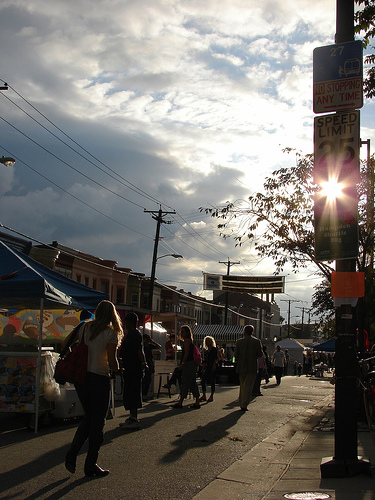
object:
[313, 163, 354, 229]
sun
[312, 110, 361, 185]
sign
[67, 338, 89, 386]
bag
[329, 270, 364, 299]
sign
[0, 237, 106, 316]
tent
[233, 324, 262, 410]
man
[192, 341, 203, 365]
backpack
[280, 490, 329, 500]
manhole cover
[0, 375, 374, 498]
sidewalk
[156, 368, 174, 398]
stool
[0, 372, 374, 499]
street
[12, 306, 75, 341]
sign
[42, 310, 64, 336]
icecream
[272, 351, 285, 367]
shirt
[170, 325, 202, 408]
people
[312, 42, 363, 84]
sign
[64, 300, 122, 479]
lady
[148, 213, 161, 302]
poles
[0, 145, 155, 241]
wires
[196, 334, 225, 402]
stand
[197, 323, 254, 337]
cover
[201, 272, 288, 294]
banner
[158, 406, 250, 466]
shadow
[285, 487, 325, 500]
manhole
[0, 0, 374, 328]
sky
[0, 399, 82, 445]
shade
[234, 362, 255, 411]
pants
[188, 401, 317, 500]
edge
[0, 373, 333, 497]
road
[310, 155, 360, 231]
glare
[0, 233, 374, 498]
market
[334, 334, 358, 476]
pole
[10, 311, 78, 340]
painting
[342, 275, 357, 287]
writing